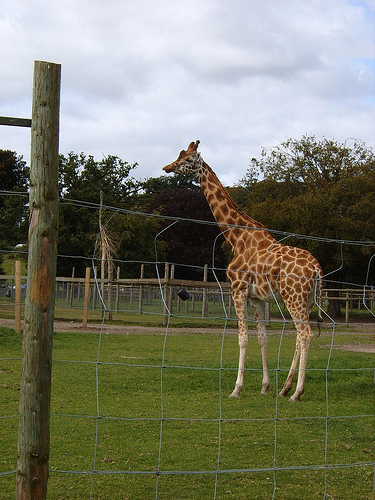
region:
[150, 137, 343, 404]
tall giraffe standing on grassland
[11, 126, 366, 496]
wired fence with wooden poles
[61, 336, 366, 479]
short trimmed grassland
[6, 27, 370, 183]
cloudy sky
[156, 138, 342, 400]
giraffe looking to the left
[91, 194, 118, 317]
tree with no leaves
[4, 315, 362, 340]
surface made of dirt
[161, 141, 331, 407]
giraffe with brown and white robe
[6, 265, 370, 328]
fence made of wooden poles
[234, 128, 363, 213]
tall tree sticking out of treeline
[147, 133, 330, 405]
This is a giraffe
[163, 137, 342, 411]
The giraffe is standing in place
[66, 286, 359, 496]
The fence is made of wire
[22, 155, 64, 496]
The wire fence is attached to wood poles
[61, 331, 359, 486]
The ground is mostly covered in grass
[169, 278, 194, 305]
Bucket hanging up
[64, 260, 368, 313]
Large structure made of wood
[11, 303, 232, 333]
Patch of dirt on the ground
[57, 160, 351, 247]
Trees outside of the fenced in area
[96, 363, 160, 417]
Square gaps in the wire fence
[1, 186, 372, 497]
The fence is metal.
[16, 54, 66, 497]
The fence post is wood.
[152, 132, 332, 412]
The giraffe is tall.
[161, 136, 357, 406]
The giraffe has a short tail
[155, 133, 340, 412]
The giraffe has four legs.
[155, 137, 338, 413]
The giraffe is standing.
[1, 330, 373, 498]
The grass is green.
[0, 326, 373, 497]
The grass is short.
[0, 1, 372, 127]
The clouds are puffy.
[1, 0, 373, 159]
The clouds are white.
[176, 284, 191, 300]
black feed barrel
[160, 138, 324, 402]
large full grown giraffe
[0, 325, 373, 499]
green grass in the giraffes pen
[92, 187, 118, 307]
dead tree with no leaves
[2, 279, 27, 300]
silver car in background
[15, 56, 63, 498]
natural wood fence post in foreground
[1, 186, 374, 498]
silver wire fencing in the foreground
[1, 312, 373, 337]
dirt path way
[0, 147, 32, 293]
large tree to the left of the car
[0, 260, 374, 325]
fencing behind the giraffe pen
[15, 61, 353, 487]
A giraffe in an enclosure.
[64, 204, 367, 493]
A fence with wire sections.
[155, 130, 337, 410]
A giraffe standing in the grass.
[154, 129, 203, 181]
The head of a giraffe.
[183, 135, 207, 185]
A giraffe standing in the grass.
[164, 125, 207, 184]
The horns on a giraffe's head.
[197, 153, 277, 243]
The mane on a giraffe's neck.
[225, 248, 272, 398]
The front legs of a giraffe.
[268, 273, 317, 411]
The back legs of a giraffe.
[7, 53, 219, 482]
Small tree trunks used as fence posts.